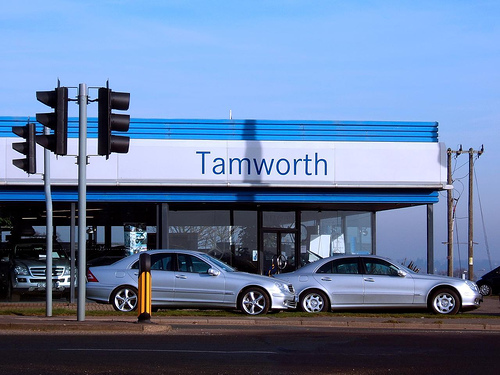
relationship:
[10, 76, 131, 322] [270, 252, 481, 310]
street lights in front of car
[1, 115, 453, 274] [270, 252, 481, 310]
dealership behind car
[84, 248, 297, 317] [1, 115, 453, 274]
car in front of dealership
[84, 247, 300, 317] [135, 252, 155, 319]
car behind post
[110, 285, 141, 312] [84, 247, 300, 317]
tire connected to car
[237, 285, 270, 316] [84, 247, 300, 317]
wheel attached to car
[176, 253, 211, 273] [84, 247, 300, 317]
window connected to car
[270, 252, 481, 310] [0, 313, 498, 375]
car next to road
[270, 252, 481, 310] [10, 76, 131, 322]
car next to street lights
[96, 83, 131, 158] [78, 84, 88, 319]
light attached to pole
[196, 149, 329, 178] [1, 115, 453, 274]
letters painted on dealership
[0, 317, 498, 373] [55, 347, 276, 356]
road has lines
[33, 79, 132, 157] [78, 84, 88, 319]
traffic lights connected to pole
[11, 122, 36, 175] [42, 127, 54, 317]
traffic light attached to pole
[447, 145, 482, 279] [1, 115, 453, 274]
powerlines behind dealership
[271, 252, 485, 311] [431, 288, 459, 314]
car has tire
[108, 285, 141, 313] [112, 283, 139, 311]
tire mounted on wheel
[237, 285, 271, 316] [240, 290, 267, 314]
wheel mounted on wheel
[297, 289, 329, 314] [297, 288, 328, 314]
tire mounted on tire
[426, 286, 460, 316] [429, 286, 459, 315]
tire mounted on tire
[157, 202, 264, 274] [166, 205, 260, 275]
frame securing window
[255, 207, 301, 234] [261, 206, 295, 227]
frame securing window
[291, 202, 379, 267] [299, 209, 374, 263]
frame securing window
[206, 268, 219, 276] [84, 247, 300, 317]
side mirror mounted on car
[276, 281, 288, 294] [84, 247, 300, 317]
headlight mounted on car